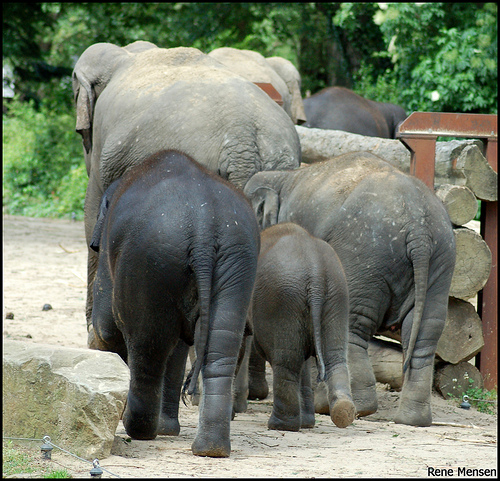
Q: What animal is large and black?
A: Elephant.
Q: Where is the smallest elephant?
A: In the middle.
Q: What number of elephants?
A: Six.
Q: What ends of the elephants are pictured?
A: Back ends.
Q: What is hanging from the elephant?
A: Tail.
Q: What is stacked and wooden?
A: Logs.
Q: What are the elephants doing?
A: Walking.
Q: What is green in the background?
A: Trees.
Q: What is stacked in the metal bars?
A: Logs of wood.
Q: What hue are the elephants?
A: Gray.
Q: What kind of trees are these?
A: Dark green.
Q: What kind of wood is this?
A: Several logs.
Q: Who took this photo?
A: Rene Mensen.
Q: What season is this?
A: Summer.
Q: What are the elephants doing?
A: Walking.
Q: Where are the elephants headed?
A: Path.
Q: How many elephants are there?
A: Six.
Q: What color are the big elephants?
A: Gray.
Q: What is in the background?
A: Trees.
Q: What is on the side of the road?
A: Logs.